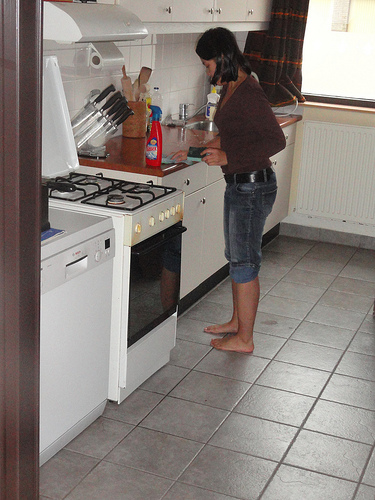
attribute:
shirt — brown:
[198, 75, 291, 179]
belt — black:
[219, 166, 275, 188]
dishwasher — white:
[38, 198, 113, 474]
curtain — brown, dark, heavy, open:
[235, 1, 318, 112]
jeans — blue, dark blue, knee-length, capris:
[213, 170, 281, 288]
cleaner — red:
[140, 101, 167, 173]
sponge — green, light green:
[186, 142, 210, 164]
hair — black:
[194, 26, 257, 91]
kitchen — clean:
[0, 0, 375, 500]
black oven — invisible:
[149, 287, 154, 294]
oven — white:
[49, 170, 187, 408]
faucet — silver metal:
[169, 91, 219, 125]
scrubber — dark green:
[188, 145, 207, 157]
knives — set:
[69, 82, 137, 150]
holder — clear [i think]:
[67, 102, 119, 159]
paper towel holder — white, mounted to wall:
[82, 40, 129, 75]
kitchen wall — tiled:
[43, 32, 252, 140]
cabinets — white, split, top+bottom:
[113, 0, 302, 319]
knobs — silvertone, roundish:
[165, 6, 294, 207]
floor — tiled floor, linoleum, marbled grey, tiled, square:
[39, 236, 371, 499]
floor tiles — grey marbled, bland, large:
[38, 234, 375, 499]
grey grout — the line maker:
[62, 235, 374, 498]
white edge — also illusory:
[177, 233, 282, 319]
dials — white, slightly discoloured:
[133, 200, 185, 242]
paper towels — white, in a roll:
[83, 49, 126, 71]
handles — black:
[83, 81, 136, 128]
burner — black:
[82, 188, 148, 213]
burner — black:
[44, 179, 101, 202]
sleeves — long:
[225, 94, 295, 166]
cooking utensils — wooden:
[114, 62, 154, 98]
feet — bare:
[201, 319, 256, 360]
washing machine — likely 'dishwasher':
[37, 200, 121, 471]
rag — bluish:
[161, 148, 196, 166]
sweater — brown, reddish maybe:
[216, 76, 291, 177]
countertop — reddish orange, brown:
[75, 107, 305, 179]